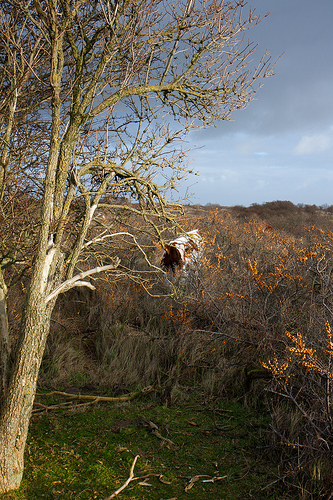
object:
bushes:
[224, 226, 333, 498]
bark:
[14, 370, 27, 449]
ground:
[140, 446, 184, 493]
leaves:
[262, 354, 296, 381]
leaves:
[286, 330, 312, 362]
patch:
[169, 240, 184, 256]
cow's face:
[153, 243, 185, 274]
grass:
[104, 322, 161, 382]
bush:
[228, 291, 289, 343]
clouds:
[281, 141, 324, 176]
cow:
[159, 226, 204, 277]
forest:
[2, 197, 333, 500]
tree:
[0, 0, 287, 499]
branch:
[101, 454, 144, 499]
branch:
[143, 414, 174, 446]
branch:
[30, 386, 153, 413]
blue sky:
[288, 11, 317, 117]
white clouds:
[192, 158, 309, 184]